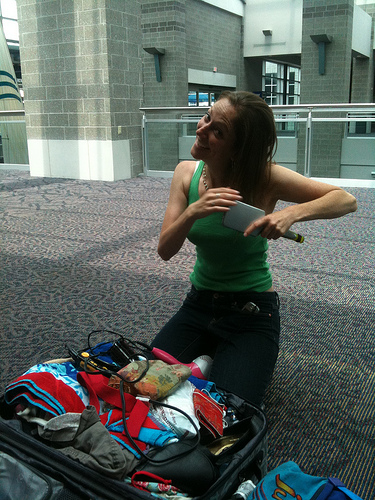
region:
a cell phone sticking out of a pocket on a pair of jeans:
[241, 300, 259, 312]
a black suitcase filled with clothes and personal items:
[2, 340, 266, 498]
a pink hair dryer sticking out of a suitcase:
[150, 344, 213, 379]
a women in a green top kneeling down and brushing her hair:
[147, 89, 359, 406]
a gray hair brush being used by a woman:
[220, 196, 303, 243]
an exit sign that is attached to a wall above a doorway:
[212, 65, 218, 72]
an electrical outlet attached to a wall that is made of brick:
[117, 124, 122, 134]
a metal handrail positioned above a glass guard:
[140, 101, 374, 111]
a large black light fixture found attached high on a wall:
[309, 31, 332, 75]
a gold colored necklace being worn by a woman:
[201, 164, 209, 191]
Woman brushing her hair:
[161, 89, 278, 296]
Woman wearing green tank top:
[182, 88, 278, 294]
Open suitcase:
[15, 335, 245, 483]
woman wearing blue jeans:
[160, 95, 278, 376]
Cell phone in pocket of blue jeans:
[171, 285, 279, 355]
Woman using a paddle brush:
[180, 85, 284, 231]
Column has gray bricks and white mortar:
[23, 5, 109, 136]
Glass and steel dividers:
[283, 103, 369, 168]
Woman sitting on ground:
[151, 89, 295, 350]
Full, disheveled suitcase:
[4, 332, 263, 486]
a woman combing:
[153, 94, 360, 320]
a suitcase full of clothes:
[0, 335, 266, 494]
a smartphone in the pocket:
[241, 300, 256, 315]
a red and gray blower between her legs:
[145, 339, 208, 373]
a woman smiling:
[156, 93, 310, 336]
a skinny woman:
[159, 88, 357, 352]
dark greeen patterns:
[0, 68, 24, 103]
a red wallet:
[191, 388, 226, 434]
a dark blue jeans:
[174, 288, 282, 369]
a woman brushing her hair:
[165, 89, 308, 246]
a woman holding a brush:
[173, 107, 309, 257]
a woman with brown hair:
[188, 91, 295, 190]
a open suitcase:
[0, 336, 296, 497]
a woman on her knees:
[143, 88, 318, 486]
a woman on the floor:
[126, 87, 330, 481]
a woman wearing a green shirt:
[147, 95, 296, 300]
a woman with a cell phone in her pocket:
[197, 122, 304, 343]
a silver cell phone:
[236, 285, 268, 328]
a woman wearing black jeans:
[158, 78, 303, 380]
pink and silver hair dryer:
[78, 350, 206, 384]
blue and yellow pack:
[251, 473, 361, 499]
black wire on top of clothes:
[114, 366, 219, 480]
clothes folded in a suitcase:
[10, 360, 187, 451]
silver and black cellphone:
[232, 299, 266, 319]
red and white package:
[191, 393, 231, 449]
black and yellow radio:
[64, 334, 102, 377]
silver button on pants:
[264, 309, 277, 319]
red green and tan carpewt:
[282, 332, 372, 458]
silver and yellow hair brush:
[200, 199, 321, 259]